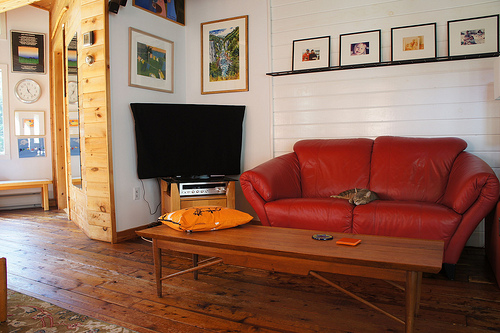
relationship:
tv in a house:
[119, 94, 263, 196] [4, 2, 499, 329]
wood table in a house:
[132, 223, 446, 333] [4, 2, 499, 329]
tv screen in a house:
[133, 100, 245, 178] [4, 2, 499, 329]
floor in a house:
[1, 202, 498, 329] [4, 2, 499, 329]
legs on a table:
[146, 251, 436, 329] [243, 192, 438, 274]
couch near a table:
[237, 132, 492, 271] [140, 219, 447, 326]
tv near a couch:
[129, 103, 246, 180] [237, 132, 492, 271]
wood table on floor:
[136, 214, 444, 330] [1, 202, 498, 329]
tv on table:
[129, 103, 246, 180] [162, 179, 237, 207]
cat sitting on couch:
[329, 185, 381, 206] [237, 132, 492, 271]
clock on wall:
[7, 71, 69, 116] [12, 5, 68, 197]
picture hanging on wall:
[197, 14, 252, 92] [183, 0, 270, 187]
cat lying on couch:
[329, 186, 381, 205] [237, 132, 492, 271]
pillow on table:
[163, 185, 277, 245] [136, 211, 429, 329]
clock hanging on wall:
[13, 76, 43, 105] [0, 1, 499, 264]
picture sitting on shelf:
[446, 14, 500, 58] [264, 56, 496, 79]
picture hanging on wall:
[446, 14, 500, 58] [1, 2, 56, 200]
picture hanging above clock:
[446, 14, 500, 58] [13, 75, 43, 102]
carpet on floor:
[4, 287, 141, 330] [0, 207, 500, 333]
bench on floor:
[2, 177, 59, 210] [0, 207, 500, 333]